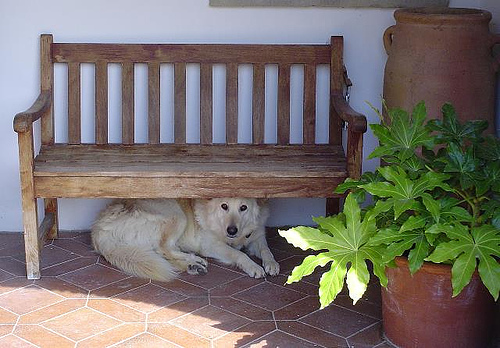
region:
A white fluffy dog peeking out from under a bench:
[92, 189, 291, 281]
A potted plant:
[283, 112, 498, 344]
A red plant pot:
[382, 257, 497, 344]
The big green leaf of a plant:
[281, 197, 388, 297]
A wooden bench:
[7, 36, 381, 284]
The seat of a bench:
[37, 140, 346, 191]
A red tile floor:
[1, 227, 375, 347]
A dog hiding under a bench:
[36, 40, 372, 281]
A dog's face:
[212, 196, 254, 239]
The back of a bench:
[43, 42, 340, 145]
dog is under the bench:
[64, 159, 292, 303]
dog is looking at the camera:
[186, 184, 263, 247]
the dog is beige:
[61, 167, 291, 297]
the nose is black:
[212, 220, 246, 244]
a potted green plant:
[343, 104, 495, 339]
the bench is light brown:
[0, 25, 376, 206]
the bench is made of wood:
[17, 31, 369, 221]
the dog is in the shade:
[95, 142, 300, 314]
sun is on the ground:
[4, 295, 239, 344]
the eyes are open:
[192, 195, 255, 220]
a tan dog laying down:
[91, 198, 280, 280]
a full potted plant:
[276, 93, 499, 346]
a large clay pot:
[376, 245, 498, 346]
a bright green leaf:
[423, 219, 498, 303]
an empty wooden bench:
[12, 33, 368, 280]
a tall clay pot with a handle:
[378, 18, 499, 258]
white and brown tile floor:
[0, 224, 390, 346]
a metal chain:
[339, 63, 351, 133]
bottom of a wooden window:
[208, 0, 449, 10]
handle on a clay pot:
[383, 18, 396, 55]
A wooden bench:
[122, 69, 295, 166]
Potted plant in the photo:
[372, 169, 487, 252]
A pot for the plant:
[377, 271, 482, 342]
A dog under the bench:
[102, 197, 283, 274]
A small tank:
[415, 42, 469, 129]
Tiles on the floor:
[148, 292, 269, 340]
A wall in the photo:
[132, 8, 219, 45]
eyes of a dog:
[215, 200, 252, 215]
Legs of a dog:
[179, 237, 279, 282]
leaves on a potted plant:
[340, 128, 497, 272]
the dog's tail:
[101, 247, 171, 281]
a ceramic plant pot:
[275, 100, 495, 340]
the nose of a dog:
[224, 224, 241, 238]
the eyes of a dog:
[217, 200, 251, 213]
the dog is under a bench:
[90, 195, 281, 280]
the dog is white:
[90, 200, 280, 280]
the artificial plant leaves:
[282, 108, 497, 301]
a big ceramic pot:
[380, 5, 497, 148]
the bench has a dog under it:
[15, 31, 366, 284]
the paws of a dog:
[244, 256, 284, 279]